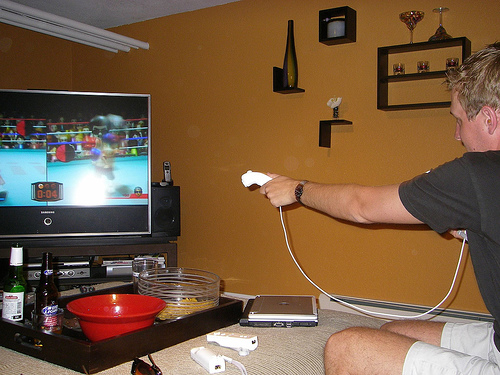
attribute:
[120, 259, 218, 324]
bowl — snack bowl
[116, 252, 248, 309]
bowl — dark brown, wooden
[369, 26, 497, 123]
shelves — black, angled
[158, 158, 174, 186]
phone — cordless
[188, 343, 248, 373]
controller — white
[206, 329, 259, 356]
controller — white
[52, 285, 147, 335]
red bowl — plastic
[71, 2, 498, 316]
wall — brown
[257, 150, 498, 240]
arm — extended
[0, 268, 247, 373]
drawer — loose